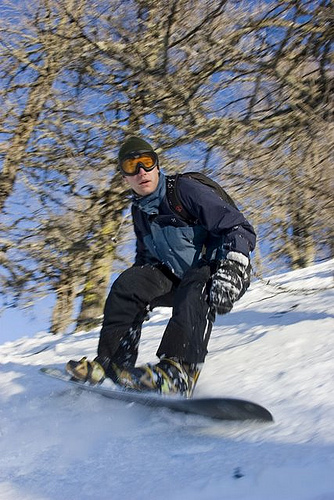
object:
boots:
[64, 353, 121, 390]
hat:
[116, 134, 156, 164]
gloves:
[199, 249, 252, 317]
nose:
[137, 166, 146, 179]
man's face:
[121, 149, 159, 197]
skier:
[64, 137, 257, 398]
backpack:
[165, 168, 241, 228]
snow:
[0, 256, 334, 499]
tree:
[0, 1, 334, 339]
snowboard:
[37, 365, 273, 424]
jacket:
[129, 168, 257, 289]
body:
[64, 175, 255, 393]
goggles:
[118, 150, 158, 178]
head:
[116, 136, 159, 197]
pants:
[96, 261, 217, 363]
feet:
[118, 351, 200, 399]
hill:
[0, 254, 334, 496]